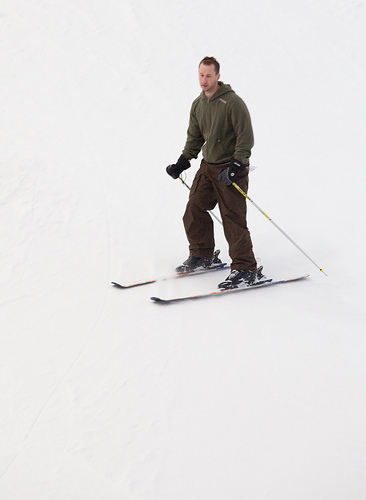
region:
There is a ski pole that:
[275, 231, 314, 292]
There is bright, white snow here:
[259, 360, 278, 429]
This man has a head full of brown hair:
[200, 48, 220, 86]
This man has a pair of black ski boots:
[228, 261, 253, 304]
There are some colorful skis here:
[161, 290, 174, 326]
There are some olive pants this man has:
[193, 169, 228, 245]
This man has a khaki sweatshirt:
[197, 94, 233, 148]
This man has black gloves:
[207, 156, 240, 207]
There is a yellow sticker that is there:
[233, 184, 248, 211]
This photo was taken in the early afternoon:
[100, 299, 214, 479]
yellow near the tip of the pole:
[317, 267, 326, 275]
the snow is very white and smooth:
[23, 302, 349, 443]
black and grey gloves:
[165, 157, 244, 186]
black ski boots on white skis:
[112, 259, 307, 300]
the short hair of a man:
[198, 56, 219, 75]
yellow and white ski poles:
[169, 170, 330, 281]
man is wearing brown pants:
[184, 163, 260, 266]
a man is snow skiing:
[112, 57, 343, 305]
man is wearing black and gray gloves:
[164, 157, 247, 185]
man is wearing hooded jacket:
[180, 64, 255, 159]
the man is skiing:
[98, 17, 351, 331]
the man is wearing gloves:
[131, 121, 269, 200]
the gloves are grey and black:
[140, 139, 270, 196]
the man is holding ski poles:
[140, 130, 333, 285]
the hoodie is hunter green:
[141, 71, 265, 163]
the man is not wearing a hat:
[176, 39, 231, 94]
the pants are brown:
[139, 147, 285, 278]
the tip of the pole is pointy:
[299, 255, 332, 284]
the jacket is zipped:
[183, 78, 233, 163]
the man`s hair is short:
[188, 40, 227, 84]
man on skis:
[121, 43, 270, 301]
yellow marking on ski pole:
[230, 179, 331, 282]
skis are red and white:
[157, 272, 299, 296]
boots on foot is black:
[228, 261, 263, 290]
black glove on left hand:
[217, 161, 243, 203]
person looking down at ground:
[187, 53, 214, 119]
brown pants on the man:
[186, 168, 259, 264]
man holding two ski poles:
[166, 178, 332, 279]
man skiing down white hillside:
[116, 40, 308, 304]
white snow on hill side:
[26, 32, 62, 71]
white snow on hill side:
[221, 409, 254, 441]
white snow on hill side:
[264, 330, 320, 384]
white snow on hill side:
[243, 386, 293, 442]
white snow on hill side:
[129, 402, 182, 455]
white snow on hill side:
[42, 366, 88, 408]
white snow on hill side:
[296, 81, 338, 122]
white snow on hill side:
[62, 129, 98, 162]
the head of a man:
[200, 47, 229, 98]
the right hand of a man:
[160, 158, 199, 182]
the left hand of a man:
[209, 157, 249, 187]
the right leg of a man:
[163, 169, 223, 264]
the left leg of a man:
[216, 179, 258, 284]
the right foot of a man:
[164, 248, 210, 283]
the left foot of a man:
[213, 255, 250, 292]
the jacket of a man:
[181, 90, 258, 156]